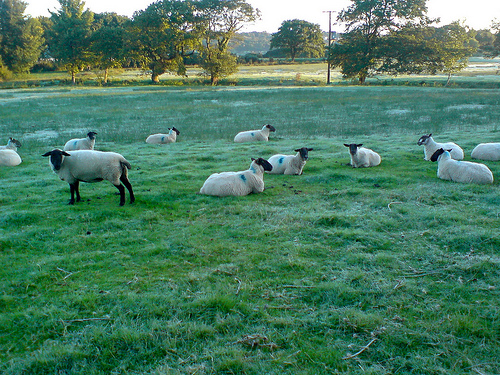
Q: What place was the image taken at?
A: It was taken at the field.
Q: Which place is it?
A: It is a field.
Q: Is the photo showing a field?
A: Yes, it is showing a field.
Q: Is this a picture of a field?
A: Yes, it is showing a field.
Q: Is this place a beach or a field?
A: It is a field.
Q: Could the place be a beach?
A: No, it is a field.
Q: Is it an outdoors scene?
A: Yes, it is outdoors.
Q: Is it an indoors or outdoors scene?
A: It is outdoors.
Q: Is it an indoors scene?
A: No, it is outdoors.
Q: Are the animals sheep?
A: Yes, all the animals are sheep.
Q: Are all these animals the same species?
A: Yes, all the animals are sheep.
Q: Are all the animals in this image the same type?
A: Yes, all the animals are sheep.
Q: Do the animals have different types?
A: No, all the animals are sheep.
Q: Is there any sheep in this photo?
A: Yes, there is a sheep.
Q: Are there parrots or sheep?
A: Yes, there is a sheep.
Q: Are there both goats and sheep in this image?
A: No, there is a sheep but no goats.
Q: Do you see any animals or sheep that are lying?
A: Yes, the sheep is lying.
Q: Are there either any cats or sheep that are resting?
A: Yes, the sheep is resting.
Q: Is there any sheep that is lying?
A: Yes, there is a sheep that is lying.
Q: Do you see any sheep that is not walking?
A: Yes, there is a sheep that is lying .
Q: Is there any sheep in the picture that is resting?
A: Yes, there is a sheep that is resting.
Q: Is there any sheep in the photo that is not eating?
A: Yes, there is a sheep that is resting.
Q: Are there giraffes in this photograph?
A: No, there are no giraffes.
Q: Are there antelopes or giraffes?
A: No, there are no giraffes or antelopes.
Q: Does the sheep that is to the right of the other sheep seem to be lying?
A: Yes, the sheep is lying.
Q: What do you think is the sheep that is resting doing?
A: The sheep is lying.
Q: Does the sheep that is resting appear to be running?
A: No, the sheep is lying.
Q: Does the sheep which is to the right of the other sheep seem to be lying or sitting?
A: The sheep is lying.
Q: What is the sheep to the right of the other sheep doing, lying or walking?
A: The sheep is lying.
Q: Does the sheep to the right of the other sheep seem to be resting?
A: Yes, the sheep is resting.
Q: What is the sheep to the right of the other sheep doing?
A: The sheep is resting.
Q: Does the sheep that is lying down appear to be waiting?
A: No, the sheep is resting.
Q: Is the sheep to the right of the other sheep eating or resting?
A: The sheep is resting.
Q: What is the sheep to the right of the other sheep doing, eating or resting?
A: The sheep is resting.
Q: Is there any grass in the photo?
A: Yes, there is grass.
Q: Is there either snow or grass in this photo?
A: Yes, there is grass.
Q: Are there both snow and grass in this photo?
A: No, there is grass but no snow.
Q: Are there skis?
A: No, there are no skis.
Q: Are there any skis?
A: No, there are no skis.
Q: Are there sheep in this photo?
A: Yes, there is a sheep.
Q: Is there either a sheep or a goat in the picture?
A: Yes, there is a sheep.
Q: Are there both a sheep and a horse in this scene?
A: No, there is a sheep but no horses.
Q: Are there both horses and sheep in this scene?
A: No, there is a sheep but no horses.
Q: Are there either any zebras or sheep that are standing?
A: Yes, the sheep is standing.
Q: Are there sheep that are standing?
A: Yes, there is a sheep that is standing.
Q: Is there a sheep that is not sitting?
A: Yes, there is a sheep that is standing.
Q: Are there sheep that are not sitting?
A: Yes, there is a sheep that is standing.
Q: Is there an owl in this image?
A: No, there are no owls.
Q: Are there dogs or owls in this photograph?
A: No, there are no owls or dogs.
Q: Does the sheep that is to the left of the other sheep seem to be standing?
A: Yes, the sheep is standing.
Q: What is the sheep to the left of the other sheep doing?
A: The sheep is standing.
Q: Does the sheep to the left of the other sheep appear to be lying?
A: No, the sheep is standing.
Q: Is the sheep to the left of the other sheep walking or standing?
A: The sheep is standing.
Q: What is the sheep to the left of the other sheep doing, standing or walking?
A: The sheep is standing.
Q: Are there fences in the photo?
A: No, there are no fences.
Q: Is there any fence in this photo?
A: No, there are no fences.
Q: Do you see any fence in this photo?
A: No, there are no fences.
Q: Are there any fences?
A: No, there are no fences.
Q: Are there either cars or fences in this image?
A: No, there are no fences or cars.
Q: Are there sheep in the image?
A: Yes, there is a sheep.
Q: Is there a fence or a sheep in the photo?
A: Yes, there is a sheep.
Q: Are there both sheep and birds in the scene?
A: No, there is a sheep but no birds.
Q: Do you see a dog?
A: No, there are no dogs.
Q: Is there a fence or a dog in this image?
A: No, there are no dogs or fences.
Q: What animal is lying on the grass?
A: The sheep is lying on the grass.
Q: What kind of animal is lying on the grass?
A: The animal is a sheep.